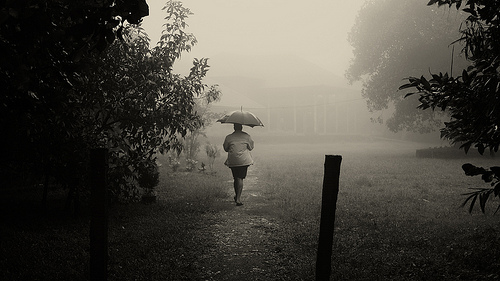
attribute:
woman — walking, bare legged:
[223, 123, 254, 206]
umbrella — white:
[217, 105, 264, 127]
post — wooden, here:
[90, 149, 109, 280]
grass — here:
[257, 141, 500, 281]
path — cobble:
[207, 146, 273, 279]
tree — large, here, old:
[345, 0, 475, 146]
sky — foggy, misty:
[146, 0, 369, 95]